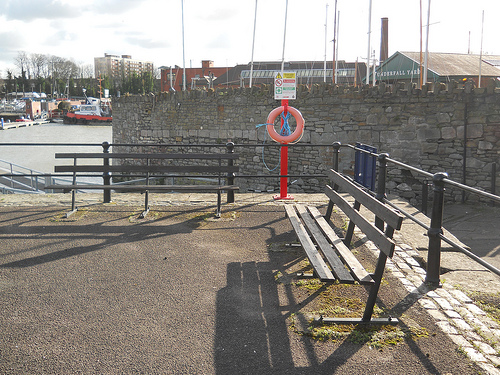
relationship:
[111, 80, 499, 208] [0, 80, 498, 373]
stone wall at harbor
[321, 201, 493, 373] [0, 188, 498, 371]
bricks on ground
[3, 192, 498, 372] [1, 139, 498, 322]
stone paving under fence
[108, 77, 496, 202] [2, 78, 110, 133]
stone wall on boat dock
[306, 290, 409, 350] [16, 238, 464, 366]
grass patch on ground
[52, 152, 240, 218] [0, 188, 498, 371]
bench on ground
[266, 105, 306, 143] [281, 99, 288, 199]
life ring on pole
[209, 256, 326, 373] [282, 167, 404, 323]
shadow of bench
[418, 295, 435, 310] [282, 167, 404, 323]
brick paver by bench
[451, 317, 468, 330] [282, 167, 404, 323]
brick paver by bench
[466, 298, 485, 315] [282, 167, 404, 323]
brick paver by bench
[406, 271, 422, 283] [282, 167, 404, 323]
brick paver by bench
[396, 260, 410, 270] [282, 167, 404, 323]
brick paver by bench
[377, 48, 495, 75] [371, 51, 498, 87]
roof on building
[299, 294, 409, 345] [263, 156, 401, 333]
grass growing under bench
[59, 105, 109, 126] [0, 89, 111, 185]
boat in harbor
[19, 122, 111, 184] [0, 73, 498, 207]
water in harbor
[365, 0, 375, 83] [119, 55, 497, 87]
sailboat beam on background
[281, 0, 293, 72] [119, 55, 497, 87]
sailboat beam on background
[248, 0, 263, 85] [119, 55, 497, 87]
sailboat beam on background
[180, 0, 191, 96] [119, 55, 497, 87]
sailboat beam on background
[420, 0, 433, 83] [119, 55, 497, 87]
sailboat beam on background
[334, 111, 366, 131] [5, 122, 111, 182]
brick by water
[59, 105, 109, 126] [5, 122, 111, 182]
boat in water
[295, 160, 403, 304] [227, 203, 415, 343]
bench on concrete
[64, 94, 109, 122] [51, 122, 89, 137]
boat on water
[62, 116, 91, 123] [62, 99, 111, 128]
tires side of boat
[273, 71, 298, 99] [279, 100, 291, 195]
sign on pole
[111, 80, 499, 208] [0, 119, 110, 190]
stone wall next to water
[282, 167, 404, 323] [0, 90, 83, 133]
bench on harbor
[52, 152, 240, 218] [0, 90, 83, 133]
bench on harbor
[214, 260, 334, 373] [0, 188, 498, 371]
shadow on ground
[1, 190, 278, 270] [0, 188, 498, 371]
shadow on ground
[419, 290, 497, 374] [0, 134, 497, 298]
bricks under fence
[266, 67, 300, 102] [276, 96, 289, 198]
sign on pole